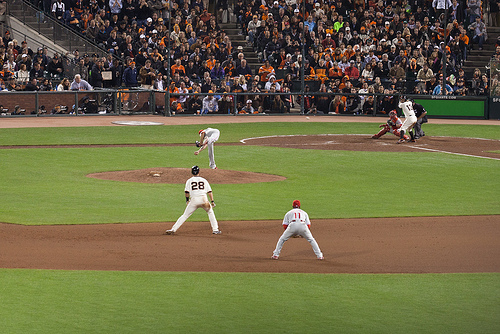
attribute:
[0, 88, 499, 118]
fence — grey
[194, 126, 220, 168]
pitcher — throwing, winding up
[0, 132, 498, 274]
diamond — green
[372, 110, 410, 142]
catcher — squatting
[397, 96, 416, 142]
batter — batting, waiting, swinging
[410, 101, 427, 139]
umpire — standing, crouched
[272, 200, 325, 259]
man — playing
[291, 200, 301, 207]
cap — red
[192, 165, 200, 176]
helmet — black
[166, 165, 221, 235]
man — leading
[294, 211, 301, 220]
number — red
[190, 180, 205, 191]
number — black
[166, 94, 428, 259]
players — playing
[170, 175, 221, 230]
uniform — white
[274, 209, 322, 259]
uniform — white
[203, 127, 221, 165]
uniform — white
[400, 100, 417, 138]
uniform — white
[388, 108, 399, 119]
helmet — red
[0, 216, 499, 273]
dirt — brown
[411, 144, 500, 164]
line — white